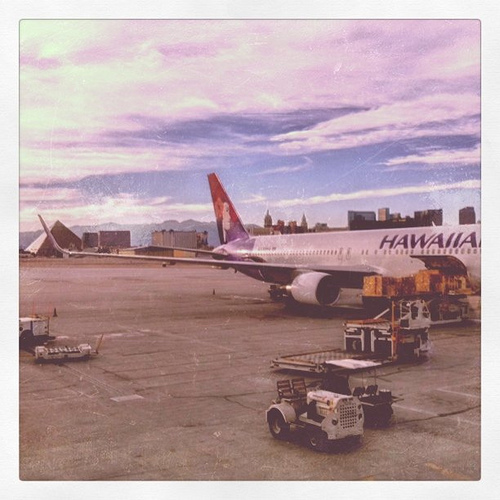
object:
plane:
[37, 172, 480, 307]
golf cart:
[265, 358, 402, 453]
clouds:
[19, 18, 479, 228]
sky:
[19, 19, 482, 229]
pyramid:
[26, 220, 85, 256]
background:
[26, 220, 83, 258]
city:
[12, 206, 480, 259]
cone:
[213, 288, 216, 296]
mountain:
[18, 220, 266, 249]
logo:
[215, 198, 231, 244]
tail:
[206, 170, 250, 246]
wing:
[37, 214, 379, 276]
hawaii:
[379, 232, 481, 250]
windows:
[233, 245, 482, 261]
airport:
[18, 21, 480, 483]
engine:
[289, 271, 341, 307]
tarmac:
[20, 254, 480, 482]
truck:
[266, 380, 366, 450]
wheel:
[267, 407, 290, 439]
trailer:
[35, 334, 106, 364]